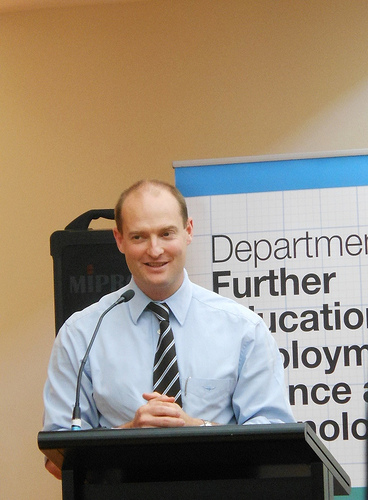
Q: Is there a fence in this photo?
A: No, there are no fences.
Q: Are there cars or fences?
A: No, there are no fences or cars.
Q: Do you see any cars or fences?
A: No, there are no fences or cars.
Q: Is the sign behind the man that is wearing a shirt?
A: Yes, the sign is behind the man.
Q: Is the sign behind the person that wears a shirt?
A: Yes, the sign is behind the man.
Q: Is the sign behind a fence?
A: No, the sign is behind the man.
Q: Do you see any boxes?
A: No, there are no boxes.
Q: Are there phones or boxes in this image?
A: No, there are no boxes or phones.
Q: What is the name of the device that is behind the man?
A: The device is a screen.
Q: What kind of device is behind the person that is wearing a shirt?
A: The device is a screen.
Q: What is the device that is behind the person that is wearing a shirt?
A: The device is a screen.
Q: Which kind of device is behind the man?
A: The device is a screen.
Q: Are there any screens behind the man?
A: Yes, there is a screen behind the man.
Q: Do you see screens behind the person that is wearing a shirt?
A: Yes, there is a screen behind the man.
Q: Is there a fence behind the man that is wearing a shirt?
A: No, there is a screen behind the man.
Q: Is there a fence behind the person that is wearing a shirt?
A: No, there is a screen behind the man.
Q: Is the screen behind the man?
A: Yes, the screen is behind the man.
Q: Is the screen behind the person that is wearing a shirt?
A: Yes, the screen is behind the man.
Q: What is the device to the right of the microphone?
A: The device is a screen.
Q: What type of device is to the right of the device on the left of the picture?
A: The device is a screen.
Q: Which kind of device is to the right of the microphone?
A: The device is a screen.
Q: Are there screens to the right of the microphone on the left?
A: Yes, there is a screen to the right of the microphone.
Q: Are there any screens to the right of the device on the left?
A: Yes, there is a screen to the right of the microphone.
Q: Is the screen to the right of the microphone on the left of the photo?
A: Yes, the screen is to the right of the microphone.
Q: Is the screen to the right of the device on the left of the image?
A: Yes, the screen is to the right of the microphone.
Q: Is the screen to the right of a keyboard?
A: No, the screen is to the right of the microphone.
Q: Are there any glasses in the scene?
A: No, there are no glasses.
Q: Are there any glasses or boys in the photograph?
A: No, there are no glasses or boys.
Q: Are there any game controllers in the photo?
A: No, there are no game controllers.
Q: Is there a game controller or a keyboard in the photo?
A: No, there are no game controllers or keyboards.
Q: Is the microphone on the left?
A: Yes, the microphone is on the left of the image.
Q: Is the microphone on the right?
A: No, the microphone is on the left of the image.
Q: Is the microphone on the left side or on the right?
A: The microphone is on the left of the image.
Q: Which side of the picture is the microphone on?
A: The microphone is on the left of the image.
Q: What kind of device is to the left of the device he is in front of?
A: The device is a microphone.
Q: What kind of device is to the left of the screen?
A: The device is a microphone.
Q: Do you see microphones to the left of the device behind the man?
A: Yes, there is a microphone to the left of the screen.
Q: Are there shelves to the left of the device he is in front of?
A: No, there is a microphone to the left of the screen.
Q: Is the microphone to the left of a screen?
A: Yes, the microphone is to the left of a screen.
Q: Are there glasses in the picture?
A: No, there are no glasses.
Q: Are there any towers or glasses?
A: No, there are no glasses or towers.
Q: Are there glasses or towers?
A: No, there are no glasses or towers.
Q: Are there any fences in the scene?
A: No, there are no fences.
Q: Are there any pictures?
A: No, there are no pictures.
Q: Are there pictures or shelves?
A: No, there are no pictures or shelves.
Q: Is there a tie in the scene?
A: Yes, there is a tie.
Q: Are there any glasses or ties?
A: Yes, there is a tie.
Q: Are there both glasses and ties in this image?
A: No, there is a tie but no glasses.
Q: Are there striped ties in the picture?
A: Yes, there is a striped tie.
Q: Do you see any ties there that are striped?
A: Yes, there is a tie that is striped.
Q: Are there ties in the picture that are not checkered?
A: Yes, there is a striped tie.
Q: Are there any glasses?
A: No, there are no glasses.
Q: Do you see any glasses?
A: No, there are no glasses.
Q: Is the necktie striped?
A: Yes, the necktie is striped.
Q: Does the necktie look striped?
A: Yes, the necktie is striped.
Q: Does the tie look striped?
A: Yes, the tie is striped.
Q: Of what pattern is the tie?
A: The tie is striped.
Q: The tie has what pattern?
A: The tie is striped.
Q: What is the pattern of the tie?
A: The tie is striped.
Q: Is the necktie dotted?
A: No, the necktie is striped.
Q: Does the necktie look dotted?
A: No, the necktie is striped.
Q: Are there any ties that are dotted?
A: No, there is a tie but it is striped.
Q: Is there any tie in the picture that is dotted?
A: No, there is a tie but it is striped.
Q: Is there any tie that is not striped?
A: No, there is a tie but it is striped.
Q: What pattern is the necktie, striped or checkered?
A: The necktie is striped.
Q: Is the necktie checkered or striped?
A: The necktie is striped.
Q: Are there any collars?
A: Yes, there is a collar.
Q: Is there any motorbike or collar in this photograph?
A: Yes, there is a collar.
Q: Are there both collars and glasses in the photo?
A: No, there is a collar but no glasses.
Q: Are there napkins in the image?
A: No, there are no napkins.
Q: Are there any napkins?
A: No, there are no napkins.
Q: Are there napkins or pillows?
A: No, there are no napkins or pillows.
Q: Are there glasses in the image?
A: No, there are no glasses.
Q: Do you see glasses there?
A: No, there are no glasses.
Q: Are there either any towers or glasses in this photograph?
A: No, there are no glasses or towers.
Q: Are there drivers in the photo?
A: No, there are no drivers.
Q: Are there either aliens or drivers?
A: No, there are no drivers or aliens.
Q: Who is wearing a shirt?
A: The man is wearing a shirt.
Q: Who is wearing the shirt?
A: The man is wearing a shirt.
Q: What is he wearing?
A: The man is wearing a shirt.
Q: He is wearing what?
A: The man is wearing a shirt.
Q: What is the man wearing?
A: The man is wearing a shirt.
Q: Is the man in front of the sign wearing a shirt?
A: Yes, the man is wearing a shirt.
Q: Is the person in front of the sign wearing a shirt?
A: Yes, the man is wearing a shirt.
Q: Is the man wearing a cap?
A: No, the man is wearing a shirt.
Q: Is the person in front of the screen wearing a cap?
A: No, the man is wearing a shirt.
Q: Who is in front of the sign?
A: The man is in front of the sign.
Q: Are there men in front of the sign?
A: Yes, there is a man in front of the sign.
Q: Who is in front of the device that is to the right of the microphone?
A: The man is in front of the screen.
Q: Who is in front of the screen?
A: The man is in front of the screen.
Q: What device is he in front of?
A: The man is in front of the screen.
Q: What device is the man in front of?
A: The man is in front of the screen.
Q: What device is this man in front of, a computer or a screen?
A: The man is in front of a screen.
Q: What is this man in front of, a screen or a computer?
A: The man is in front of a screen.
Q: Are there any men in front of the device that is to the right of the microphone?
A: Yes, there is a man in front of the screen.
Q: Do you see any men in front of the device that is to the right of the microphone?
A: Yes, there is a man in front of the screen.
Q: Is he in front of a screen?
A: Yes, the man is in front of a screen.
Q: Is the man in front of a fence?
A: No, the man is in front of a screen.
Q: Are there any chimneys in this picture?
A: No, there are no chimneys.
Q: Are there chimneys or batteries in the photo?
A: No, there are no chimneys or batteries.